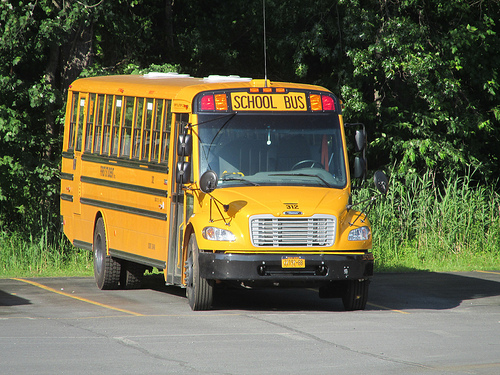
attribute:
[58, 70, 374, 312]
bus — school bus, large, yellow, parked, vacant, handicap accessible, lonely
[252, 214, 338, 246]
grill — gray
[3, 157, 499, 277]
grass — tall, green, thick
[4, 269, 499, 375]
parking lot — paved, gray, hot, steamy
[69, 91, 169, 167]
windows — small, passenger windows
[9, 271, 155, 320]
line — yellow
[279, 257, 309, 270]
license plate — yellow, blue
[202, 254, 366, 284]
bumper — front bumper, black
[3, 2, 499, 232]
bushes — green